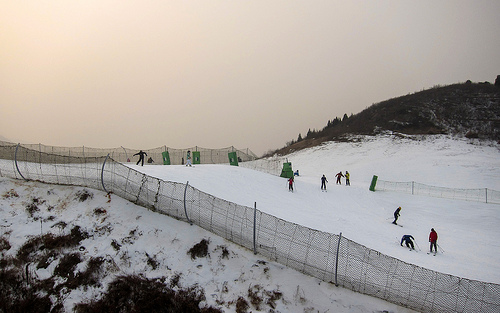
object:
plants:
[0, 187, 281, 313]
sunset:
[8, 7, 221, 143]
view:
[0, 121, 500, 311]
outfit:
[320, 174, 328, 192]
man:
[392, 206, 402, 225]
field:
[167, 136, 484, 274]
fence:
[0, 143, 500, 312]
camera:
[0, 49, 494, 312]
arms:
[335, 171, 346, 185]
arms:
[344, 171, 350, 187]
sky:
[3, 5, 473, 158]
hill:
[0, 75, 500, 313]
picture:
[4, 3, 500, 313]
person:
[426, 228, 438, 256]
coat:
[429, 231, 438, 242]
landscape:
[0, 78, 500, 313]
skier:
[392, 206, 401, 225]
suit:
[428, 231, 437, 252]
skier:
[426, 228, 437, 256]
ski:
[400, 235, 421, 253]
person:
[133, 150, 147, 166]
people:
[400, 234, 415, 251]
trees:
[311, 128, 318, 139]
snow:
[3, 130, 495, 311]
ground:
[2, 129, 498, 311]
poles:
[434, 243, 437, 254]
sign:
[280, 162, 294, 179]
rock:
[186, 236, 211, 262]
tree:
[342, 113, 349, 121]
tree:
[327, 120, 331, 127]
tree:
[297, 133, 302, 142]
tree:
[291, 139, 294, 145]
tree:
[307, 128, 312, 137]